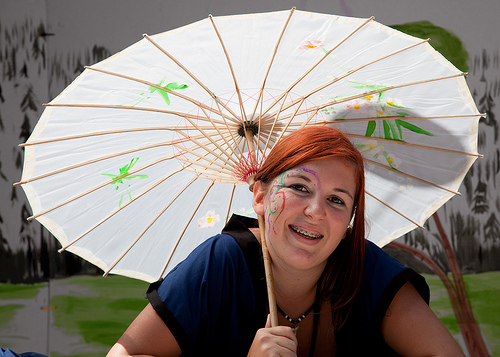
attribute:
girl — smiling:
[103, 127, 467, 355]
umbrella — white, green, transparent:
[12, 5, 487, 327]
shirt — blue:
[145, 214, 431, 356]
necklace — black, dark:
[268, 296, 323, 335]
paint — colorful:
[266, 165, 319, 236]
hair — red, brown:
[255, 124, 365, 333]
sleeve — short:
[146, 233, 232, 356]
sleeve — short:
[358, 237, 430, 356]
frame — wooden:
[13, 6, 488, 283]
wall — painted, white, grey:
[0, 0, 499, 356]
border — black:
[147, 279, 189, 356]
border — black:
[223, 212, 271, 329]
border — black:
[372, 267, 431, 353]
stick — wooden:
[246, 130, 279, 327]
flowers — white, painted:
[350, 81, 438, 143]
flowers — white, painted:
[298, 37, 329, 56]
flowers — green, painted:
[144, 78, 188, 104]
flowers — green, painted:
[105, 160, 149, 205]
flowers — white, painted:
[192, 209, 226, 230]